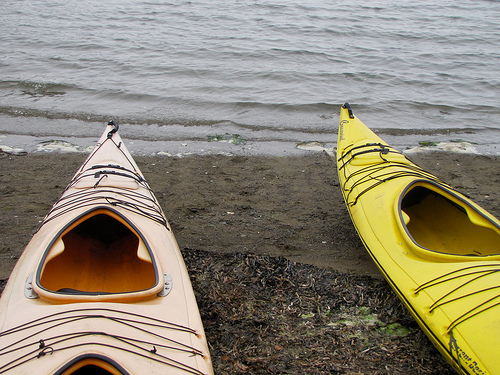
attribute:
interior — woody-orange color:
[50, 210, 157, 293]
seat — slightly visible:
[58, 283, 118, 302]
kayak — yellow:
[333, 128, 494, 333]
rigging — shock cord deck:
[3, 306, 207, 370]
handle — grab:
[97, 116, 119, 145]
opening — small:
[392, 175, 483, 261]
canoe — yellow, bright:
[338, 106, 498, 373]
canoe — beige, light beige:
[0, 120, 212, 372]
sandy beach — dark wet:
[3, 98, 481, 370]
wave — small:
[1, 127, 334, 143]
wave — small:
[1, 103, 484, 134]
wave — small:
[1, 78, 484, 114]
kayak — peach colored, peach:
[2, 119, 225, 372]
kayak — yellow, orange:
[332, 95, 494, 371]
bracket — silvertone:
[28, 202, 163, 306]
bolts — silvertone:
[156, 271, 175, 300]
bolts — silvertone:
[21, 275, 42, 304]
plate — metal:
[154, 270, 172, 299]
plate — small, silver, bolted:
[159, 261, 173, 307]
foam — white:
[27, 132, 67, 153]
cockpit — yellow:
[395, 172, 484, 264]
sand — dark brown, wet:
[1, 146, 497, 368]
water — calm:
[6, 3, 496, 165]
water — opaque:
[154, 34, 368, 117]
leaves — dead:
[227, 277, 401, 349]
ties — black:
[52, 151, 187, 220]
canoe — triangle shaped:
[28, 175, 178, 347]